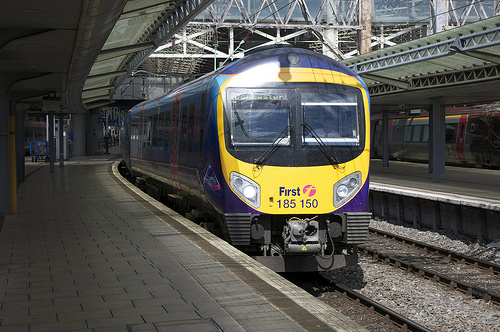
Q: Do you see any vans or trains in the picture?
A: Yes, there is a train.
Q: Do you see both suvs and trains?
A: No, there is a train but no suvs.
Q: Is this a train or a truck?
A: This is a train.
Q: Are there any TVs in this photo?
A: No, there are no tvs.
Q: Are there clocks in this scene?
A: No, there are no clocks.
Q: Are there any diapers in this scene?
A: No, there are no diapers.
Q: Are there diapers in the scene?
A: No, there are no diapers.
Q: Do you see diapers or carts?
A: No, there are no diapers or carts.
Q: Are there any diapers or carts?
A: No, there are no diapers or carts.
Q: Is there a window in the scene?
A: Yes, there is a window.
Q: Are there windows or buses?
A: Yes, there is a window.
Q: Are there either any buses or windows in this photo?
A: Yes, there is a window.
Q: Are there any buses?
A: No, there are no buses.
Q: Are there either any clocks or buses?
A: No, there are no buses or clocks.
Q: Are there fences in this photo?
A: No, there are no fences.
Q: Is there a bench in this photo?
A: No, there are no benches.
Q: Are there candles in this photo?
A: No, there are no candles.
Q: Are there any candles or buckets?
A: No, there are no candles or buckets.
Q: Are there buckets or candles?
A: No, there are no candles or buckets.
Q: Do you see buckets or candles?
A: No, there are no candles or buckets.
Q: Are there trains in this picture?
A: Yes, there is a train.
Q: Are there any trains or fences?
A: Yes, there is a train.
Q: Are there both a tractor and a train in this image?
A: No, there is a train but no tractors.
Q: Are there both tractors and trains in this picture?
A: No, there is a train but no tractors.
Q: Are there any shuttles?
A: No, there are no shuttles.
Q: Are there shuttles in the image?
A: No, there are no shuttles.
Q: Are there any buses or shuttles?
A: No, there are no shuttles or buses.